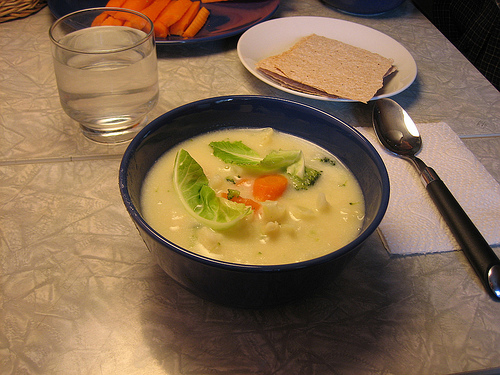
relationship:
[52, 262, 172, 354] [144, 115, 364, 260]
table has food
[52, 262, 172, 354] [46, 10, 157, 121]
table has drink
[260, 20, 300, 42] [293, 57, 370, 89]
saucer has bread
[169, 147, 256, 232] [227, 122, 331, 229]
appetizer in soup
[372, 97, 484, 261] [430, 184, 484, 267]
spoon has a black handle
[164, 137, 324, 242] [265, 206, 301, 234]
soup has noodles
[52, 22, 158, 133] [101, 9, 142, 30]
water in a glass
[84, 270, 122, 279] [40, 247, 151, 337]
line on a table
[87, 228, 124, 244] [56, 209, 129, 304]
line on a table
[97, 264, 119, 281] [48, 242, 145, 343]
line on a table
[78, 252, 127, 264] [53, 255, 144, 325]
line on a table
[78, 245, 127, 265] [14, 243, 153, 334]
line on a table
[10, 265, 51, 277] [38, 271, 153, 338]
line on a table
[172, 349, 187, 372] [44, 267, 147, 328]
line on a table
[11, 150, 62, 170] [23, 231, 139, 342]
line on a table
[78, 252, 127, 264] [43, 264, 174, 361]
line on a table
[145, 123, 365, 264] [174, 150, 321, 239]
soup has vegetables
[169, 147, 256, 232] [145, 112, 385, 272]
appetizer in soup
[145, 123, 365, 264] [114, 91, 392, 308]
soup in plate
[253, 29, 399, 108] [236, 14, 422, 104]
bread in bowl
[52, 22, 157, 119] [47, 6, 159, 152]
water in cup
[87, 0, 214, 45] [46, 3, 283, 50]
carrots in plate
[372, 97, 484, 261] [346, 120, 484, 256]
spoon on napkin